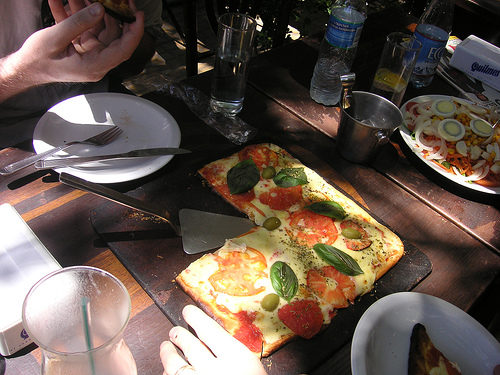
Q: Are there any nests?
A: No, there are no nests.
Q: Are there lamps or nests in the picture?
A: No, there are no nests or lamps.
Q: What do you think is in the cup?
A: The straw is in the cup.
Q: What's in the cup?
A: The straw is in the cup.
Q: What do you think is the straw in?
A: The straw is in the cup.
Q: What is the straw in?
A: The straw is in the cup.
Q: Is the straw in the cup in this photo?
A: Yes, the straw is in the cup.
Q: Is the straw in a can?
A: No, the straw is in the cup.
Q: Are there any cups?
A: Yes, there is a cup.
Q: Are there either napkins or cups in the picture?
A: Yes, there is a cup.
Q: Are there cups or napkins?
A: Yes, there is a cup.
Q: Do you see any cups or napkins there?
A: Yes, there is a cup.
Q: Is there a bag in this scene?
A: No, there are no bags.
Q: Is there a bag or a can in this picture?
A: No, there are no bags or cans.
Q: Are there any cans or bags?
A: No, there are no bags or cans.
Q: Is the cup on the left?
A: Yes, the cup is on the left of the image.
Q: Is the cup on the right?
A: No, the cup is on the left of the image.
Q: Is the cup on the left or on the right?
A: The cup is on the left of the image.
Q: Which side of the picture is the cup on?
A: The cup is on the left of the image.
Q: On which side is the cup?
A: The cup is on the left of the image.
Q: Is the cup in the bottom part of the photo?
A: Yes, the cup is in the bottom of the image.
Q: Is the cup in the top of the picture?
A: No, the cup is in the bottom of the image.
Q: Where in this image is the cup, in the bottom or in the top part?
A: The cup is in the bottom of the image.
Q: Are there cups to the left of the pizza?
A: Yes, there is a cup to the left of the pizza.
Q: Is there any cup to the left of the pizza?
A: Yes, there is a cup to the left of the pizza.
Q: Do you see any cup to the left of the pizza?
A: Yes, there is a cup to the left of the pizza.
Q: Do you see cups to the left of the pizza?
A: Yes, there is a cup to the left of the pizza.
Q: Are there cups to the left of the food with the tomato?
A: Yes, there is a cup to the left of the pizza.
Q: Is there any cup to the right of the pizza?
A: No, the cup is to the left of the pizza.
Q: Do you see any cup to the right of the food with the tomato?
A: No, the cup is to the left of the pizza.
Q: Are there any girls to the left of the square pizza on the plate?
A: No, there is a cup to the left of the pizza.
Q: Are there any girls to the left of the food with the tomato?
A: No, there is a cup to the left of the pizza.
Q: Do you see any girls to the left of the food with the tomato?
A: No, there is a cup to the left of the pizza.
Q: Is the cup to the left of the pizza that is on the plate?
A: Yes, the cup is to the left of the pizza.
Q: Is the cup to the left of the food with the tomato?
A: Yes, the cup is to the left of the pizza.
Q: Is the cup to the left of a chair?
A: No, the cup is to the left of the pizza.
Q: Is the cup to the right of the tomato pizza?
A: No, the cup is to the left of the pizza.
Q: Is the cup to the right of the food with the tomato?
A: No, the cup is to the left of the pizza.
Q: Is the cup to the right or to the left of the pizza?
A: The cup is to the left of the pizza.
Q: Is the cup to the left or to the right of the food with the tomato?
A: The cup is to the left of the pizza.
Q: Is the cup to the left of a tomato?
A: Yes, the cup is to the left of a tomato.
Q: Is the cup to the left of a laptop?
A: No, the cup is to the left of a tomato.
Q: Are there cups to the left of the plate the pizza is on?
A: Yes, there is a cup to the left of the plate.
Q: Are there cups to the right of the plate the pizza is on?
A: No, the cup is to the left of the plate.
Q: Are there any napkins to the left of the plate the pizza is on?
A: No, there is a cup to the left of the plate.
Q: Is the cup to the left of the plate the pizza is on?
A: Yes, the cup is to the left of the plate.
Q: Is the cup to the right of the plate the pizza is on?
A: No, the cup is to the left of the plate.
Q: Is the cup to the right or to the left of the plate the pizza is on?
A: The cup is to the left of the plate.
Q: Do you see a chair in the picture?
A: No, there are no chairs.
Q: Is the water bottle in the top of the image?
A: Yes, the water bottle is in the top of the image.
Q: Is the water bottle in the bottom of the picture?
A: No, the water bottle is in the top of the image.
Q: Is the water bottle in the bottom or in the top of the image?
A: The water bottle is in the top of the image.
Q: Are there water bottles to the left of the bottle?
A: Yes, there is a water bottle to the left of the bottle.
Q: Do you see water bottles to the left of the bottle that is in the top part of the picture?
A: Yes, there is a water bottle to the left of the bottle.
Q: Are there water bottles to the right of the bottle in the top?
A: No, the water bottle is to the left of the bottle.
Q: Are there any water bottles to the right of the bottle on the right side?
A: No, the water bottle is to the left of the bottle.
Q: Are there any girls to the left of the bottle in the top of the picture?
A: No, there is a water bottle to the left of the bottle.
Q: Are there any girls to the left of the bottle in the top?
A: No, there is a water bottle to the left of the bottle.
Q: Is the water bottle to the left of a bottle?
A: Yes, the water bottle is to the left of a bottle.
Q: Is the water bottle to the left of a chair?
A: No, the water bottle is to the left of a bottle.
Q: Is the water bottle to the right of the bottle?
A: No, the water bottle is to the left of the bottle.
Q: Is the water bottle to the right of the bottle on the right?
A: No, the water bottle is to the left of the bottle.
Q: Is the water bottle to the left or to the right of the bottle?
A: The water bottle is to the left of the bottle.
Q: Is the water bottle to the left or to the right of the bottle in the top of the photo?
A: The water bottle is to the left of the bottle.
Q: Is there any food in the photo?
A: Yes, there is food.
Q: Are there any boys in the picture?
A: No, there are no boys.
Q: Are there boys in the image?
A: No, there are no boys.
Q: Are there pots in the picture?
A: No, there are no pots.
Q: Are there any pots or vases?
A: No, there are no pots or vases.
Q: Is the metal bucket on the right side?
A: Yes, the bucket is on the right of the image.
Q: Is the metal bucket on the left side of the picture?
A: No, the bucket is on the right of the image.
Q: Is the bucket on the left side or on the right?
A: The bucket is on the right of the image.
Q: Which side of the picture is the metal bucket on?
A: The bucket is on the right of the image.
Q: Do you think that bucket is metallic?
A: Yes, the bucket is metallic.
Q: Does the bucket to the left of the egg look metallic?
A: Yes, the bucket is metallic.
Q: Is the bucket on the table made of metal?
A: Yes, the bucket is made of metal.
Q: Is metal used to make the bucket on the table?
A: Yes, the bucket is made of metal.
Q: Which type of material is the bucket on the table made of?
A: The bucket is made of metal.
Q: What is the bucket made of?
A: The bucket is made of metal.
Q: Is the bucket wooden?
A: No, the bucket is metallic.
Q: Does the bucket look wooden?
A: No, the bucket is metallic.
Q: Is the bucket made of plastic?
A: No, the bucket is made of metal.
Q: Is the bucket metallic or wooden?
A: The bucket is metallic.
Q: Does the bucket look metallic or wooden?
A: The bucket is metallic.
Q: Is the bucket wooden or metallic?
A: The bucket is metallic.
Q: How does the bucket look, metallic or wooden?
A: The bucket is metallic.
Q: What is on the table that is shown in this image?
A: The bucket is on the table.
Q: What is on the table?
A: The bucket is on the table.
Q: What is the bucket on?
A: The bucket is on the table.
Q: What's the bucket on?
A: The bucket is on the table.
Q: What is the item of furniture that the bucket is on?
A: The piece of furniture is a table.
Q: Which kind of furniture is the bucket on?
A: The bucket is on the table.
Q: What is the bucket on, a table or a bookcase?
A: The bucket is on a table.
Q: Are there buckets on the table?
A: Yes, there is a bucket on the table.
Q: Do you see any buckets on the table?
A: Yes, there is a bucket on the table.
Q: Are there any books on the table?
A: No, there is a bucket on the table.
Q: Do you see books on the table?
A: No, there is a bucket on the table.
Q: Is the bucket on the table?
A: Yes, the bucket is on the table.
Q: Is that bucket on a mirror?
A: No, the bucket is on the table.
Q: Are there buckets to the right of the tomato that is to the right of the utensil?
A: Yes, there is a bucket to the right of the tomato.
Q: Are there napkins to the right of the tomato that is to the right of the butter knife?
A: No, there is a bucket to the right of the tomato.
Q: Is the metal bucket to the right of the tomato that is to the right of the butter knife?
A: Yes, the bucket is to the right of the tomato.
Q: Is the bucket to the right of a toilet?
A: No, the bucket is to the right of the tomato.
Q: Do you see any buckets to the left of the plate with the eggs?
A: Yes, there is a bucket to the left of the plate.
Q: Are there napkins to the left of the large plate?
A: No, there is a bucket to the left of the plate.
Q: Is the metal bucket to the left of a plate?
A: Yes, the bucket is to the left of a plate.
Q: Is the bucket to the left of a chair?
A: No, the bucket is to the left of a plate.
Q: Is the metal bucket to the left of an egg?
A: Yes, the bucket is to the left of an egg.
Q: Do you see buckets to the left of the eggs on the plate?
A: Yes, there is a bucket to the left of the eggs.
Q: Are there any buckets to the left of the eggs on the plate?
A: Yes, there is a bucket to the left of the eggs.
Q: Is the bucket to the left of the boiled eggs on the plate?
A: Yes, the bucket is to the left of the eggs.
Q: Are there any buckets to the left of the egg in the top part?
A: Yes, there is a bucket to the left of the egg.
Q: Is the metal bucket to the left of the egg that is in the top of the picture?
A: Yes, the bucket is to the left of the egg.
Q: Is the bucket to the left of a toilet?
A: No, the bucket is to the left of the egg.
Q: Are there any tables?
A: Yes, there is a table.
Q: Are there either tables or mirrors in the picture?
A: Yes, there is a table.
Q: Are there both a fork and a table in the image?
A: Yes, there are both a table and a fork.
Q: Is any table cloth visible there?
A: No, there are no tablecloths.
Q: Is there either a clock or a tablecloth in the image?
A: No, there are no tablecloths or clocks.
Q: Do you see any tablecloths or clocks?
A: No, there are no tablecloths or clocks.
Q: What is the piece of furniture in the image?
A: The piece of furniture is a table.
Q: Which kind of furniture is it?
A: The piece of furniture is a table.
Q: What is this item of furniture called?
A: This is a table.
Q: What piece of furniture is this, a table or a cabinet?
A: This is a table.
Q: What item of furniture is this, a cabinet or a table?
A: This is a table.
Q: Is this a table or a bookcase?
A: This is a table.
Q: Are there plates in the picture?
A: Yes, there is a plate.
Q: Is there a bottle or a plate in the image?
A: Yes, there is a plate.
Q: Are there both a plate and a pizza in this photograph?
A: Yes, there are both a plate and a pizza.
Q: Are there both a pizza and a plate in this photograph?
A: Yes, there are both a plate and a pizza.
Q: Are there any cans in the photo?
A: No, there are no cans.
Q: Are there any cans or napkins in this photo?
A: No, there are no cans or napkins.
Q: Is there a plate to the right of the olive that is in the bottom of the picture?
A: Yes, there is a plate to the right of the olive.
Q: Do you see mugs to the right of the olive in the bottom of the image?
A: No, there is a plate to the right of the olive.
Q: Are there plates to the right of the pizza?
A: Yes, there is a plate to the right of the pizza.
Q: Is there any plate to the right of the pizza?
A: Yes, there is a plate to the right of the pizza.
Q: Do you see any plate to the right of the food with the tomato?
A: Yes, there is a plate to the right of the pizza.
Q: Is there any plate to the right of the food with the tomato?
A: Yes, there is a plate to the right of the pizza.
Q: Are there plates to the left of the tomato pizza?
A: No, the plate is to the right of the pizza.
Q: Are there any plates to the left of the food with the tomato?
A: No, the plate is to the right of the pizza.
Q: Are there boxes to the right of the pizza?
A: No, there is a plate to the right of the pizza.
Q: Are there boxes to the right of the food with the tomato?
A: No, there is a plate to the right of the pizza.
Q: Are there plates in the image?
A: Yes, there is a plate.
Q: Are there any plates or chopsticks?
A: Yes, there is a plate.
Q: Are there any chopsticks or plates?
A: Yes, there is a plate.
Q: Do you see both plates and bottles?
A: Yes, there are both a plate and a bottle.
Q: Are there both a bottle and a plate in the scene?
A: Yes, there are both a plate and a bottle.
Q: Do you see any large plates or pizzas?
A: Yes, there is a large plate.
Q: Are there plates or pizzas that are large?
A: Yes, the plate is large.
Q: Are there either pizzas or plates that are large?
A: Yes, the plate is large.